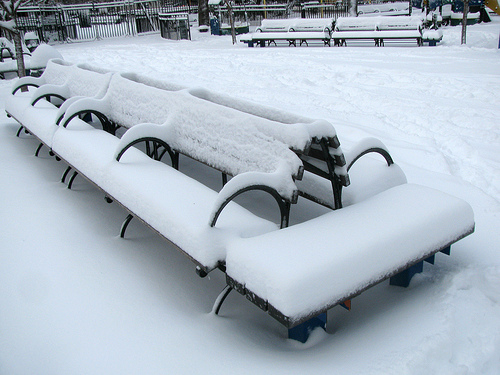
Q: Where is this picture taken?
A: A park.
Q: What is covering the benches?
A: Snow.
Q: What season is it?
A: Winter.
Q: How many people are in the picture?
A: None.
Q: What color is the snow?
A: White.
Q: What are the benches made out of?
A: Wood.